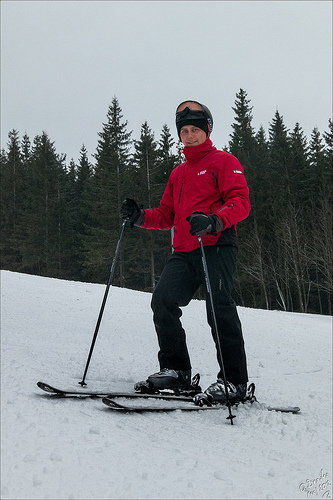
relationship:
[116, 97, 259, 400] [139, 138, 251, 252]
man wearing jacket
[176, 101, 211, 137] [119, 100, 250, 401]
hat worn by man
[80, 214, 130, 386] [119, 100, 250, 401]
stick held by man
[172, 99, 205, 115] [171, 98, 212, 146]
goggles on a head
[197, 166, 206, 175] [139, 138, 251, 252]
logo on jacket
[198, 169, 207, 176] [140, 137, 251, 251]
logo on front of jacket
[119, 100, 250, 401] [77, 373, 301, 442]
man on skiis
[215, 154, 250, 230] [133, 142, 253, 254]
sleeve of jacket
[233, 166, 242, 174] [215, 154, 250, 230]
logo on sleeve